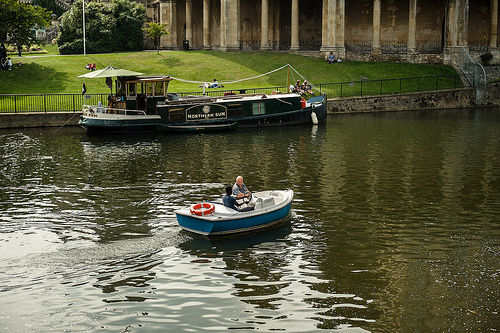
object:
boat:
[176, 188, 293, 237]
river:
[2, 104, 499, 332]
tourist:
[233, 175, 248, 198]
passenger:
[231, 178, 251, 212]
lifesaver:
[189, 203, 213, 217]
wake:
[4, 184, 328, 327]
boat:
[78, 64, 328, 132]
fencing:
[0, 72, 474, 113]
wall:
[0, 86, 475, 134]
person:
[328, 52, 337, 63]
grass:
[0, 48, 462, 114]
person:
[199, 78, 216, 89]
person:
[85, 63, 96, 69]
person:
[4, 57, 11, 70]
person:
[300, 81, 315, 95]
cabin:
[114, 74, 173, 114]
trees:
[0, 0, 56, 62]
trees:
[141, 21, 169, 55]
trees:
[51, 0, 163, 56]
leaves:
[142, 20, 171, 38]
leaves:
[0, 0, 53, 58]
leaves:
[54, 0, 159, 53]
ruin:
[141, 2, 499, 64]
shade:
[2, 62, 63, 101]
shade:
[196, 50, 467, 94]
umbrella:
[78, 65, 145, 79]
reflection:
[0, 109, 499, 332]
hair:
[236, 175, 244, 181]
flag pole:
[82, 0, 87, 55]